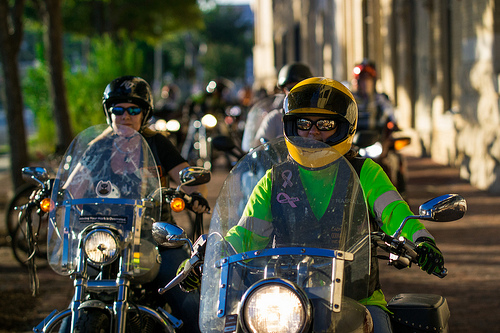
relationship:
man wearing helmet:
[175, 77, 443, 332] [282, 75, 359, 170]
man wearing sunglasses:
[175, 77, 443, 332] [294, 118, 341, 132]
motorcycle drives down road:
[29, 123, 212, 331] [1, 157, 498, 333]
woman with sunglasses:
[21, 77, 208, 325] [108, 105, 144, 117]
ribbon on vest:
[282, 168, 294, 188] [267, 157, 379, 299]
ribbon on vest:
[277, 192, 299, 208] [267, 157, 379, 299]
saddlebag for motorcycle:
[388, 293, 452, 333] [157, 138, 467, 333]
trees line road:
[1, 1, 203, 189] [1, 157, 498, 333]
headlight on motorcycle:
[237, 278, 312, 333] [157, 138, 467, 333]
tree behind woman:
[0, 0, 202, 196] [21, 77, 208, 325]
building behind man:
[251, 2, 294, 93] [175, 77, 443, 332]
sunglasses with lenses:
[108, 105, 144, 117] [113, 104, 143, 114]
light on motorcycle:
[82, 227, 121, 267] [29, 123, 212, 331]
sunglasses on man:
[294, 118, 341, 132] [175, 77, 443, 332]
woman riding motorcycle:
[21, 77, 208, 325] [29, 123, 212, 331]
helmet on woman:
[103, 78, 153, 118] [21, 77, 208, 325]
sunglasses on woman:
[108, 105, 144, 117] [21, 77, 208, 325]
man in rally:
[175, 77, 443, 332] [6, 62, 467, 333]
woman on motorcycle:
[21, 77, 208, 325] [29, 123, 212, 331]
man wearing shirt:
[175, 77, 443, 332] [225, 157, 431, 314]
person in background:
[179, 80, 241, 165] [0, 0, 499, 185]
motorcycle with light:
[29, 123, 212, 331] [82, 227, 121, 267]